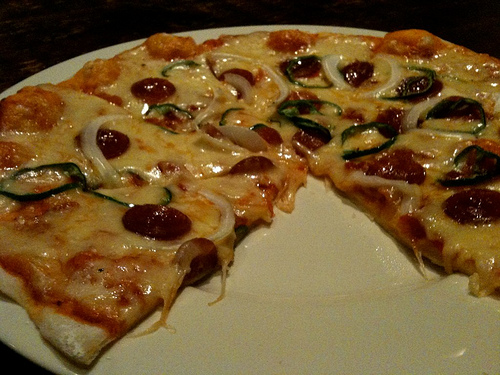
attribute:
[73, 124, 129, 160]
pepperoni — red, round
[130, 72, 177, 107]
pepperoni — red, round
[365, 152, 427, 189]
pepperoni — red, round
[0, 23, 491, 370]
dinner plate — white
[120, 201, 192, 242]
pepperoni — red, round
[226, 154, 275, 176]
pepperoni — red, round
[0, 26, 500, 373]
pizza — piece of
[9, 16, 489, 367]
plate — white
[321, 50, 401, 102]
sliver onion — cooked, white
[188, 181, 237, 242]
sliver onion — white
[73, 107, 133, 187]
sliver onion — white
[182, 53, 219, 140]
sliver onion — white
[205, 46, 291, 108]
sliver onion — white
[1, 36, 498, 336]
cheese — melted